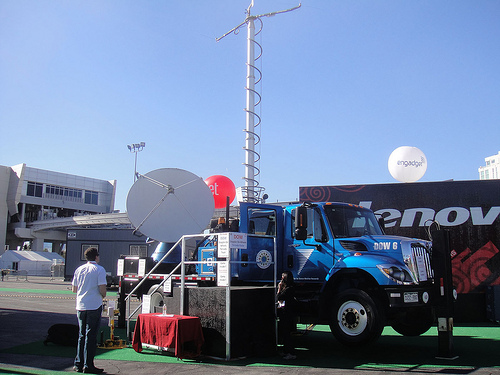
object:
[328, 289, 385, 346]
tire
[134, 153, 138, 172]
pole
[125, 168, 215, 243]
dish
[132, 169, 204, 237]
satellite dish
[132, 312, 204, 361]
table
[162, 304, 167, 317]
bottle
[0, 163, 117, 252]
building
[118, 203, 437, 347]
blue truck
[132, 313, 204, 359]
cloth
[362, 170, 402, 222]
ground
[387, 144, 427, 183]
balloons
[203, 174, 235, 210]
balloon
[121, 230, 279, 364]
staircase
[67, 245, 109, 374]
man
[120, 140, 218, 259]
satellite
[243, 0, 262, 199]
pole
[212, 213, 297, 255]
floor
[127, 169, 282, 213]
floor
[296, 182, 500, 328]
sign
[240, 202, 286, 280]
door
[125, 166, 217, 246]
radar dish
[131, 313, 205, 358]
covering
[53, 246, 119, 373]
lady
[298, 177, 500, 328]
board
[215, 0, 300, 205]
antennae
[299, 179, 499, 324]
advertisement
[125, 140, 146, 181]
lights